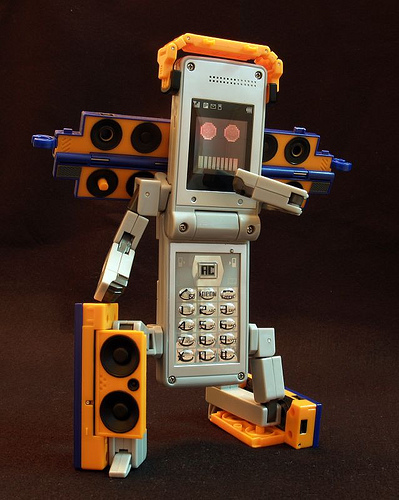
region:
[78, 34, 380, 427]
a robot cell phone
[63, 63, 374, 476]
a robot flip phone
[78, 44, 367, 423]
a robot silver phone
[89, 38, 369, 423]
a robot silver cell phone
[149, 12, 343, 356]
a robot silver flip pohne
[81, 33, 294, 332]
a phone that is open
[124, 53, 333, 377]
a flip phone that is open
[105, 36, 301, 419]
a cellphone that is open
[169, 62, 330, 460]
a silver phone that is open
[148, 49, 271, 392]
open silver cell phone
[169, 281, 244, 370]
buttons on front of cell phone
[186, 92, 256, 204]
display screen on front of cell phone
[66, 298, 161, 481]
orange and blue robotic legs on bottom of cell phone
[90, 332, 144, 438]
black speakers on front of orange robotic legs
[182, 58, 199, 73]
screw at top corner of cell phone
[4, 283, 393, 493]
textured dark table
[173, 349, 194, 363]
asterick button on bottom corner of silver cell phone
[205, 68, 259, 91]
speaker holes on front of silver cell phone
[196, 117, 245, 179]
robot face on cell phone screen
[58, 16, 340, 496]
a robot made fo cellphone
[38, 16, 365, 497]
a robot made fo cellphone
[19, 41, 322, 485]
a robot made fo cellphone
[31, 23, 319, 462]
a robot made fo cellphone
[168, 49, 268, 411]
the cellphone is gray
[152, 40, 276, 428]
the cellphone is gray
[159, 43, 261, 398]
the cellphone is gray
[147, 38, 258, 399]
the cellphone is gray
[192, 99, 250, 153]
eyes of the object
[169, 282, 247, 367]
numbers on the object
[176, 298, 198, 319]
the number one on object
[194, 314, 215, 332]
the number 5 on object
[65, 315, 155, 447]
yellow leg of item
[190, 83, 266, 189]
screen of the object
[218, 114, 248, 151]
round light on object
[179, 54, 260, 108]
top part of the phone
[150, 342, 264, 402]
bottom of the phone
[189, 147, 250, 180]
mouth of the item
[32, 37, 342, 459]
Toy Cellphone is yellow and blue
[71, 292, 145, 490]
toy leg is made of a speaker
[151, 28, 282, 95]
toy with a yellow helmet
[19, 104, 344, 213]
toy wing is yellow and blue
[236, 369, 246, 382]
small screw on the toy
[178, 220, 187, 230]
small screw on the toy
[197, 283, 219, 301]
button on front of phone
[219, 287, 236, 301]
button on front of phone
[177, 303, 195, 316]
button on front of phone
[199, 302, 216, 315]
button on front of phone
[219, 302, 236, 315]
button on front of phone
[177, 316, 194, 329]
button on front of phone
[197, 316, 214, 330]
button on front of phone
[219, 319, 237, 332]
button on front of phone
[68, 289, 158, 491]
leg of robot phone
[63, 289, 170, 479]
leg of robot phone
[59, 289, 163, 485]
leg of robot phone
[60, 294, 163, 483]
leg of robot phone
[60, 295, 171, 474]
leg of robot phone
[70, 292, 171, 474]
leg of robot phone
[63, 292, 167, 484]
leg of robot phone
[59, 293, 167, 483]
leg of robot phone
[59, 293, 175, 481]
leg of robot phone